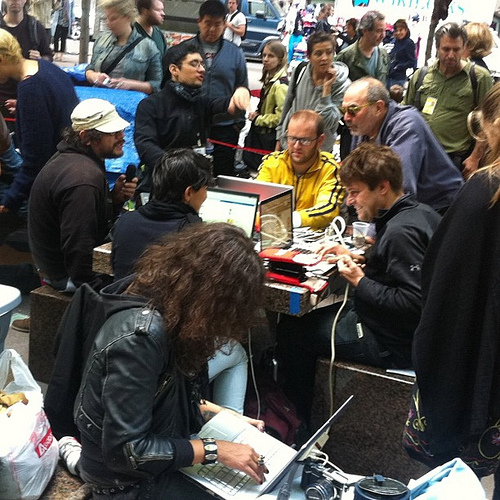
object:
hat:
[70, 97, 132, 134]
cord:
[328, 284, 351, 420]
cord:
[248, 325, 262, 420]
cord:
[306, 448, 351, 488]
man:
[132, 40, 251, 212]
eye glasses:
[176, 58, 205, 67]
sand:
[313, 71, 326, 86]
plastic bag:
[0, 348, 62, 500]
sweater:
[1, 57, 79, 214]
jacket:
[354, 192, 441, 371]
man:
[26, 97, 140, 296]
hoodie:
[274, 59, 351, 155]